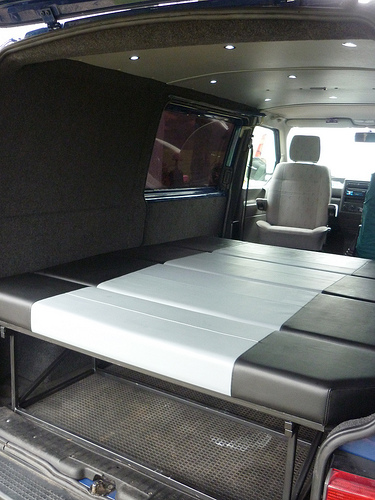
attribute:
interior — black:
[23, 364, 317, 499]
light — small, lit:
[333, 38, 355, 51]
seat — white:
[253, 129, 343, 252]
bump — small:
[95, 404, 101, 408]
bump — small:
[173, 429, 180, 435]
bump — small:
[99, 430, 105, 434]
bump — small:
[235, 446, 239, 451]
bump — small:
[265, 457, 273, 462]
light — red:
[307, 464, 371, 499]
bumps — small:
[57, 383, 205, 459]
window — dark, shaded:
[141, 89, 249, 203]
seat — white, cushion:
[252, 132, 332, 250]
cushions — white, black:
[3, 235, 373, 420]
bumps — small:
[27, 372, 314, 498]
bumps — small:
[120, 410, 146, 430]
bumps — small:
[0, 457, 69, 497]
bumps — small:
[239, 300, 305, 310]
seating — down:
[1, 236, 373, 427]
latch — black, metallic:
[34, 3, 66, 30]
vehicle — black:
[1, 1, 373, 497]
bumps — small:
[21, 364, 326, 499]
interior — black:
[14, 62, 352, 481]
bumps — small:
[35, 359, 296, 497]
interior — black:
[1, 0, 373, 499]